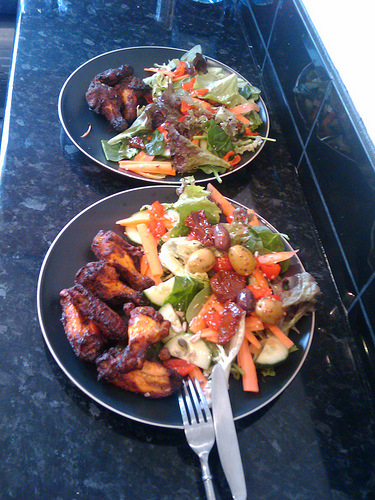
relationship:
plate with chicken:
[23, 188, 323, 406] [56, 240, 168, 375]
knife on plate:
[208, 362, 247, 499] [37, 183, 315, 428]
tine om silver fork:
[196, 376, 212, 419] [173, 377, 217, 497]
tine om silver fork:
[186, 376, 204, 422] [173, 377, 217, 497]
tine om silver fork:
[183, 382, 198, 423] [173, 377, 217, 497]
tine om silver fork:
[174, 383, 190, 424] [173, 377, 217, 497]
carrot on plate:
[207, 181, 239, 223] [37, 183, 315, 428]